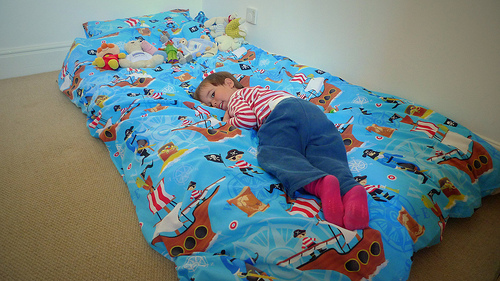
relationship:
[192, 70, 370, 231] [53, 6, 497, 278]
boy on bed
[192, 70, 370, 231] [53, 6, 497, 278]
boy lying on bed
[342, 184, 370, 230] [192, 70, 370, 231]
sock on a boy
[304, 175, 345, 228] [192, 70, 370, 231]
sock on a boy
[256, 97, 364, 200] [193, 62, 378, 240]
pants on a child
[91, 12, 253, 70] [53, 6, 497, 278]
stuffed animals on bed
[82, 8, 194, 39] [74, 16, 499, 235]
pillow on bed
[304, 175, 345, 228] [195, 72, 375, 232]
sock on boy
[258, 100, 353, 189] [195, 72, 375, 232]
pajamas on boy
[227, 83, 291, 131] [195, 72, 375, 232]
shirt on boy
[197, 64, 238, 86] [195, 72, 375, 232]
hair on boy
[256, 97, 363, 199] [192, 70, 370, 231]
pants on boy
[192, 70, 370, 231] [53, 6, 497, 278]
boy laying on bed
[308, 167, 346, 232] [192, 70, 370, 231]
sock on boy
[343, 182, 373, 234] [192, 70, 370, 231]
sock on boy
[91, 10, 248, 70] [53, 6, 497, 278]
stuffed animals on bed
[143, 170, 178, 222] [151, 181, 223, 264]
sail on boat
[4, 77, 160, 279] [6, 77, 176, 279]
carpet on floor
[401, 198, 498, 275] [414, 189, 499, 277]
carpet on floor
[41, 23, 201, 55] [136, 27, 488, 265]
pillow above comforter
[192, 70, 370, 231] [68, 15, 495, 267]
boy laying on bed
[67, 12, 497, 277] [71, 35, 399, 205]
pirate design on bed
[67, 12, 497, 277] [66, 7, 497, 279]
pirate design on cover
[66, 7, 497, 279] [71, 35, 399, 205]
cover on bed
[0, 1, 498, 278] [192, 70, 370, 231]
bedroom with boy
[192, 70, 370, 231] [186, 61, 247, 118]
boy has head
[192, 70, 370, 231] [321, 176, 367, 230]
boy has feet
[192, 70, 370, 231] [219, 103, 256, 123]
boy has elbow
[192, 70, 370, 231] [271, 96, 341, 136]
boy has butt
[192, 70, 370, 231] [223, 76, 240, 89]
boy has ear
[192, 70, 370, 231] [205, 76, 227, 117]
boy has eyes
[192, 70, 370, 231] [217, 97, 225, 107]
boy has mouth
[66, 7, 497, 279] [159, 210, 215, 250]
cover has design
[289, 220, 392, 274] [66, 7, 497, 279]
pirate ship on cover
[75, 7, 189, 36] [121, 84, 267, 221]
pillow matching bed cover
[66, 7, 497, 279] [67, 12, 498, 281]
cover has pirate design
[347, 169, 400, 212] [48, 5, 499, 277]
pirate on comforter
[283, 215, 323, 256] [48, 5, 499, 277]
pirate on comforter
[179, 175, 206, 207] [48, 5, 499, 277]
pirate on comforter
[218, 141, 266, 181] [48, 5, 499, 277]
pirate on comforter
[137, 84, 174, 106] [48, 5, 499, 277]
pirate on comforter